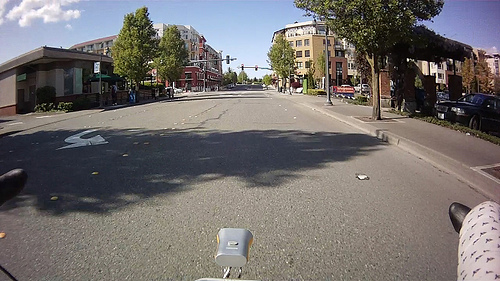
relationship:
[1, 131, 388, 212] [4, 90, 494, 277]
shadow on street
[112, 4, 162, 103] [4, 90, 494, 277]
tree lining street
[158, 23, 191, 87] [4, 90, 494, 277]
tree lining street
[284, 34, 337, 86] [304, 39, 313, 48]
building has window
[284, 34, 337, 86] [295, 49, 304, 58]
building has window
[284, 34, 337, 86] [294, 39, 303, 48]
building has window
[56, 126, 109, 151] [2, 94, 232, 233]
arrow in lane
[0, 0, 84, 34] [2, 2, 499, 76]
cloud in sky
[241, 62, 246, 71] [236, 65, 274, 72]
signal on post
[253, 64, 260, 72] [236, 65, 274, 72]
signal on post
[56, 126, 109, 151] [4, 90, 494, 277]
arrow on street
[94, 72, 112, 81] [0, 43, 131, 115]
awning on building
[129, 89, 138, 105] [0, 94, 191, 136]
trashcan on sidewalk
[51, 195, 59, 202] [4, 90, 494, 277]
reflector on street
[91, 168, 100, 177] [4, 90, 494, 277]
reflector on street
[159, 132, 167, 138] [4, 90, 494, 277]
reflector on street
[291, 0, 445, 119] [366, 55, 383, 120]
tree has trunk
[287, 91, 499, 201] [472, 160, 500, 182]
sidewalk has part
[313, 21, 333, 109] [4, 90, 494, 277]
lamp for street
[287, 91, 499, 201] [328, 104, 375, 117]
sidewalk has part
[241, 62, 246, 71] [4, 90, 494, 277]
signal above street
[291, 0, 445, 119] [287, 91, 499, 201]
tree on sidewalk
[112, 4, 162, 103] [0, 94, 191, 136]
tree on sidewalk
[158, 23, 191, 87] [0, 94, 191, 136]
tree on sidewalk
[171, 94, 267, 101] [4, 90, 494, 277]
shadow on street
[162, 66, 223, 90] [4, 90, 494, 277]
building side of street